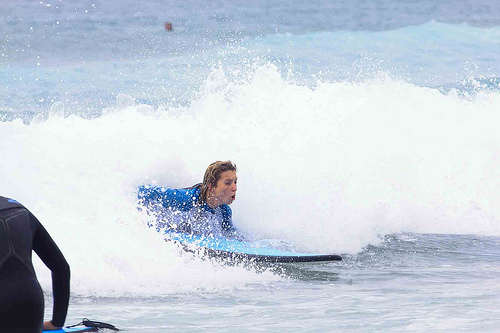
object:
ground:
[423, 138, 442, 162]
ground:
[352, 107, 384, 171]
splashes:
[193, 23, 261, 68]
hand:
[43, 314, 54, 326]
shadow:
[254, 263, 341, 283]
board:
[32, 318, 119, 331]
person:
[139, 160, 239, 242]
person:
[0, 192, 71, 329]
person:
[162, 20, 175, 33]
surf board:
[162, 236, 349, 264]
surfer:
[135, 160, 241, 246]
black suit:
[1, 195, 72, 332]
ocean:
[0, 2, 498, 331]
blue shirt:
[137, 185, 235, 232]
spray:
[242, 58, 499, 201]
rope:
[68, 319, 111, 328]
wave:
[0, 48, 498, 300]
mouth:
[230, 195, 237, 201]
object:
[160, 21, 178, 35]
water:
[1, 11, 481, 323]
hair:
[197, 160, 238, 199]